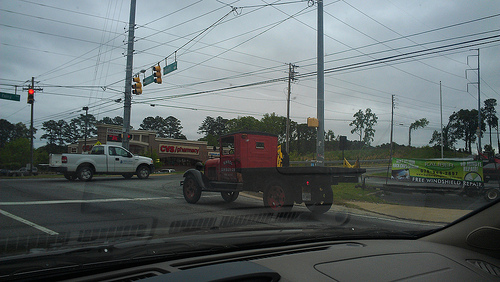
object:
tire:
[77, 166, 94, 181]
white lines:
[0, 209, 60, 235]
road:
[5, 166, 432, 266]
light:
[28, 100, 33, 104]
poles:
[438, 81, 443, 158]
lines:
[38, 9, 479, 66]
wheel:
[122, 173, 133, 179]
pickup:
[48, 144, 155, 182]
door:
[219, 135, 237, 182]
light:
[28, 94, 34, 98]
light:
[133, 88, 142, 95]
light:
[153, 66, 161, 71]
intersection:
[0, 173, 201, 207]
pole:
[313, 0, 324, 157]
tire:
[64, 172, 78, 181]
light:
[28, 89, 34, 95]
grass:
[337, 180, 367, 206]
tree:
[348, 108, 378, 149]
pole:
[475, 48, 481, 159]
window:
[109, 147, 128, 157]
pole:
[389, 95, 394, 157]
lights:
[153, 72, 161, 77]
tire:
[137, 165, 151, 179]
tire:
[221, 191, 239, 201]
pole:
[286, 62, 292, 153]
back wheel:
[305, 179, 333, 214]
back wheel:
[263, 179, 295, 217]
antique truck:
[180, 131, 367, 217]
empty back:
[242, 132, 352, 168]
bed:
[240, 166, 367, 177]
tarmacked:
[36, 193, 113, 215]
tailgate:
[48, 165, 67, 173]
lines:
[0, 196, 185, 206]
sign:
[390, 156, 484, 189]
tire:
[183, 171, 202, 203]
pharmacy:
[68, 124, 208, 172]